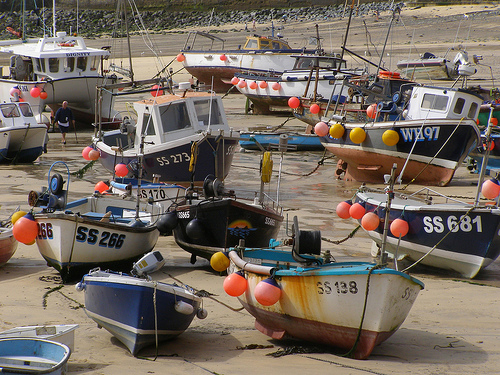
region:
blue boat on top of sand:
[80, 266, 200, 356]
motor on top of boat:
[130, 246, 165, 276]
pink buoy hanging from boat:
[250, 270, 276, 305]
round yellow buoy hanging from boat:
[206, 250, 227, 261]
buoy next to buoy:
[220, 266, 246, 291]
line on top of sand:
[296, 350, 381, 370]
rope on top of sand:
[161, 266, 241, 306]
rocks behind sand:
[0, 2, 401, 35]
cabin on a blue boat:
[131, 91, 232, 149]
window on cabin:
[194, 100, 221, 124]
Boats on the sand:
[0, 0, 498, 373]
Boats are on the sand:
[0, 0, 498, 373]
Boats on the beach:
[0, 0, 499, 373]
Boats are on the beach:
[0, 1, 499, 373]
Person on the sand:
[50, 98, 82, 148]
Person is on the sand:
[52, 96, 82, 147]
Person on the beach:
[54, 95, 77, 144]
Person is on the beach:
[50, 95, 88, 145]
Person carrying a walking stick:
[67, 117, 82, 143]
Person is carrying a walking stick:
[70, 117, 82, 144]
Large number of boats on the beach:
[1, 36, 492, 343]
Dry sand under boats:
[0, 22, 498, 372]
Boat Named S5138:
[195, 236, 420, 356]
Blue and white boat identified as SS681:
[335, 168, 496, 290]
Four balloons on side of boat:
[330, 193, 418, 248]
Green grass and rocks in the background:
[0, 0, 348, 21]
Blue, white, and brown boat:
[314, 75, 478, 182]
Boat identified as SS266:
[22, 178, 172, 290]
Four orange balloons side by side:
[228, 75, 288, 96]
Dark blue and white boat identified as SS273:
[82, 76, 233, 194]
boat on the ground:
[228, 238, 421, 353]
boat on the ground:
[84, 261, 196, 347]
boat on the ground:
[349, 184, 496, 281]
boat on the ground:
[52, 201, 169, 267]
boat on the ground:
[151, 193, 294, 246]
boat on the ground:
[285, 86, 478, 183]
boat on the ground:
[89, 102, 235, 183]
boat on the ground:
[95, 179, 188, 214]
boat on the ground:
[232, 55, 359, 103]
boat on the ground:
[2, 30, 129, 101]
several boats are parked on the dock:
[69, 39, 332, 351]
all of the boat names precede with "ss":
[31, 211, 273, 324]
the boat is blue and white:
[35, 240, 271, 367]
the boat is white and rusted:
[205, 248, 410, 371]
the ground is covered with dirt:
[199, 280, 274, 370]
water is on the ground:
[252, 150, 374, 256]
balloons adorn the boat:
[280, 91, 477, 226]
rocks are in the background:
[100, 13, 252, 64]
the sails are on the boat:
[106, 13, 194, 110]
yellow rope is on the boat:
[238, 136, 288, 215]